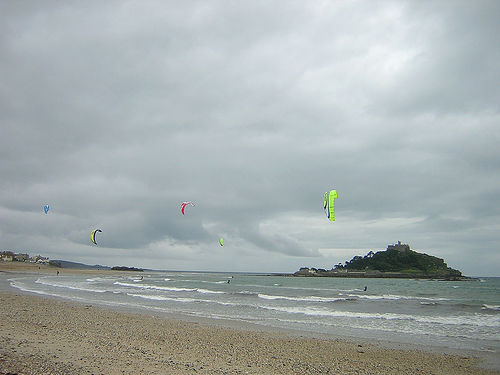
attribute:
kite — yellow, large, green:
[317, 187, 346, 224]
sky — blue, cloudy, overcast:
[2, 1, 498, 280]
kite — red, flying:
[177, 196, 193, 218]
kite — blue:
[42, 203, 52, 214]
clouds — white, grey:
[0, 3, 491, 276]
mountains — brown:
[297, 239, 468, 280]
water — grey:
[12, 272, 498, 352]